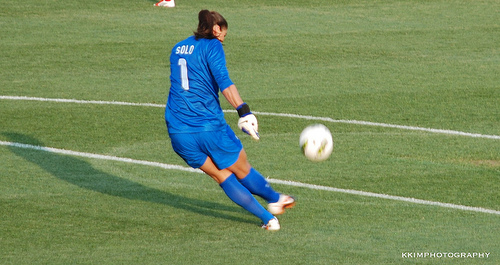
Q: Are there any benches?
A: No, there are no benches.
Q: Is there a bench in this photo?
A: No, there are no benches.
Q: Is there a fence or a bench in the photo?
A: No, there are no benches or fences.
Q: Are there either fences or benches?
A: No, there are no benches or fences.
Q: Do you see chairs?
A: No, there are no chairs.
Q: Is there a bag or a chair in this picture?
A: No, there are no chairs or bags.